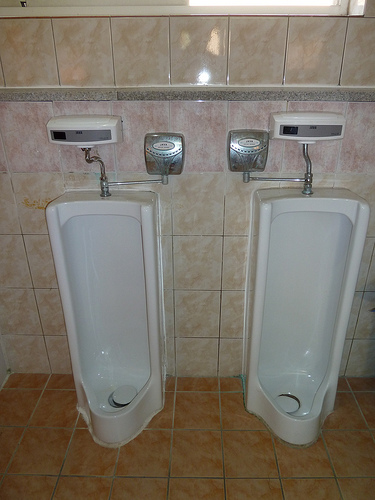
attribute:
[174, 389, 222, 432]
tile — orange, brown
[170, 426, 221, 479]
tile — orange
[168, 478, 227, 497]
tile — orange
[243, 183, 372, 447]
urinal — white, tall, toilet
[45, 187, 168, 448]
urinal — white, tall, clean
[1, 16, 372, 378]
wall — white, marble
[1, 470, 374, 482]
grout — dirty